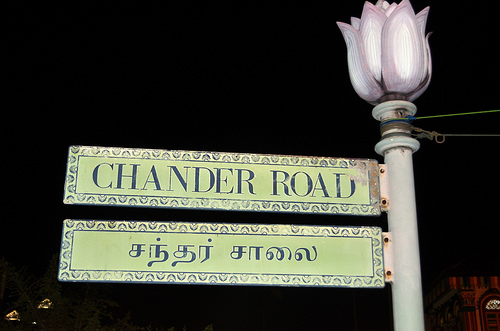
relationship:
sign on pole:
[60, 144, 384, 219] [133, 96, 498, 297]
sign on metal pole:
[60, 144, 384, 219] [367, 98, 424, 331]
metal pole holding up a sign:
[367, 98, 424, 331] [47, 123, 390, 302]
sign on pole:
[60, 144, 384, 219] [372, 100, 426, 330]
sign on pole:
[54, 218, 385, 288] [372, 100, 426, 330]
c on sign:
[86, 156, 117, 193] [52, 135, 387, 215]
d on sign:
[189, 163, 217, 193] [52, 135, 387, 215]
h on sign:
[112, 158, 143, 191] [57, 133, 398, 226]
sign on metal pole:
[60, 144, 384, 219] [346, 107, 438, 315]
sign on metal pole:
[60, 144, 384, 219] [359, 105, 433, 328]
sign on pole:
[60, 144, 384, 219] [371, 109, 438, 329]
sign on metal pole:
[60, 144, 384, 219] [369, 100, 440, 330]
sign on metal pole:
[54, 218, 385, 288] [369, 100, 440, 330]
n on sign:
[164, 156, 191, 202] [60, 144, 384, 219]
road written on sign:
[269, 165, 362, 204] [52, 135, 387, 215]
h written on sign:
[114, 162, 141, 190] [81, 152, 371, 287]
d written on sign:
[189, 166, 216, 193] [60, 144, 384, 219]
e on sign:
[210, 166, 237, 193] [60, 144, 384, 219]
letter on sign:
[232, 165, 259, 198] [60, 144, 384, 219]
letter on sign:
[269, 169, 292, 199] [60, 144, 384, 219]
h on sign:
[114, 162, 141, 190] [46, 140, 334, 213]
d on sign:
[189, 166, 216, 193] [108, 131, 407, 233]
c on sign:
[93, 161, 117, 189] [60, 144, 384, 219]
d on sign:
[189, 166, 216, 193] [60, 144, 384, 219]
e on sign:
[210, 166, 237, 193] [48, 145, 410, 291]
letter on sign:
[232, 165, 259, 198] [52, 135, 387, 215]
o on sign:
[291, 171, 312, 196] [60, 144, 384, 219]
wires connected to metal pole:
[417, 105, 499, 142] [367, 98, 424, 331]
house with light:
[1, 260, 96, 330] [35, 294, 58, 312]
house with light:
[1, 260, 96, 330] [4, 307, 20, 321]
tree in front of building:
[6, 298, 59, 324] [424, 261, 500, 331]